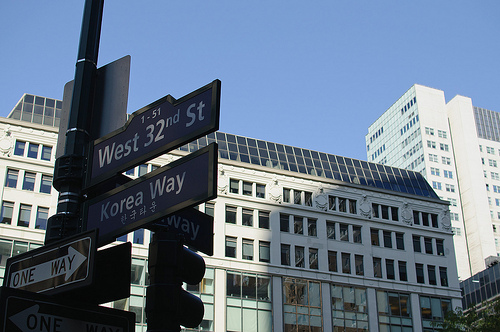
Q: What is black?
A: Sign.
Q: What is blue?
A: Sky.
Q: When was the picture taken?
A: Daytime.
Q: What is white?
A: Letters.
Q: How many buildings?
A: Two.